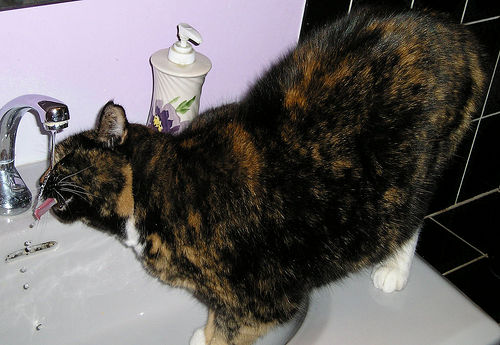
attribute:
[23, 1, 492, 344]
cat — in the photo, black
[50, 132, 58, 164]
water — in the photo, falling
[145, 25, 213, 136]
bottle — white, plastic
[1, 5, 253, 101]
wall — white, clean, tiles, purple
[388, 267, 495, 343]
washbasin — white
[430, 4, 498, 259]
tiles — black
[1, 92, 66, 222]
facuet — on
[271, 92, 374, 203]
fur — black, brown